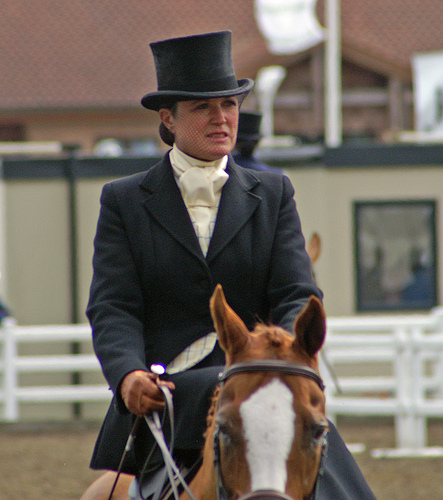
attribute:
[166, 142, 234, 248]
tie — cream colored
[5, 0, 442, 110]
roof — rust colored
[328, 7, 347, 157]
white pole — white 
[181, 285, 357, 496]
horse — white , brown 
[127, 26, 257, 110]
top hat — black 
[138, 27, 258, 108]
black hat — black 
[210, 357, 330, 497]
dark straps — Dark 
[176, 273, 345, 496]
horse — large 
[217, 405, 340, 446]
eyes — Dark 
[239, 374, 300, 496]
marking — white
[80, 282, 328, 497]
horse — brown, white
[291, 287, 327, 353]
ear — brown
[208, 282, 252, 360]
ear — brown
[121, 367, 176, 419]
glove — brown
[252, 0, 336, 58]
flag — white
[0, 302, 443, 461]
fence — white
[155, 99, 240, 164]
netting — black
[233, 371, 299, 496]
coloring — white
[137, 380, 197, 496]
reigns — black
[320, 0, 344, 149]
pole — small, thin, white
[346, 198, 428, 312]
picture — black, framed, blurry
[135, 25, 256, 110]
hat — black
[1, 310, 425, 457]
fence — white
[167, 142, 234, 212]
bow tie — beige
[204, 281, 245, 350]
ear — horse